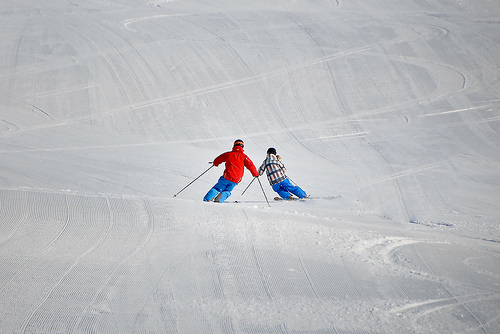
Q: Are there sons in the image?
A: No, there are no sons.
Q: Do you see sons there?
A: No, there are no sons.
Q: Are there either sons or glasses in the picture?
A: No, there are no sons or glasses.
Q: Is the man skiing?
A: Yes, the man is skiing.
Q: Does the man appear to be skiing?
A: Yes, the man is skiing.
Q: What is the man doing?
A: The man is skiing.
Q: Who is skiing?
A: The man is skiing.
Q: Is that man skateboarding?
A: No, the man is skiing.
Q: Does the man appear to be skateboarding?
A: No, the man is skiing.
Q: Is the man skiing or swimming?
A: The man is skiing.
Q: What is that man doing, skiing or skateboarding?
A: The man is skiing.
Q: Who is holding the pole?
A: The man is holding the pole.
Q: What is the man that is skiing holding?
A: The man is holding the pole.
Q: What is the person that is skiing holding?
A: The man is holding the pole.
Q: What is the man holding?
A: The man is holding the pole.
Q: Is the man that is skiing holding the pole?
A: Yes, the man is holding the pole.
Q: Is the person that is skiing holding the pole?
A: Yes, the man is holding the pole.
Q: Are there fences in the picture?
A: No, there are no fences.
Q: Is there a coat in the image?
A: Yes, there is a coat.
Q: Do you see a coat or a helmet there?
A: Yes, there is a coat.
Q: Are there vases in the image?
A: No, there are no vases.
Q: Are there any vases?
A: No, there are no vases.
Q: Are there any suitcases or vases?
A: No, there are no vases or suitcases.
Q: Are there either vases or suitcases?
A: No, there are no vases or suitcases.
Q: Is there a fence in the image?
A: No, there are no fences.